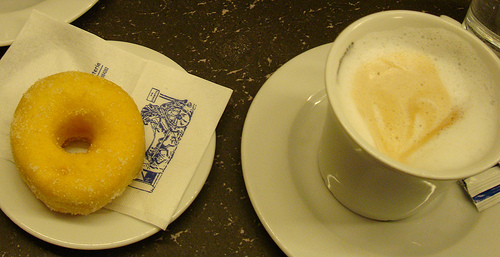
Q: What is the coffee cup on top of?
A: A plate.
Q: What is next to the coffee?
A: A packet of sugar.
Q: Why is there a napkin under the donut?
A: So the customer can hold the donut.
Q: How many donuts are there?
A: One.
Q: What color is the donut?
A: Golden brown.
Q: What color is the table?
A: Black.